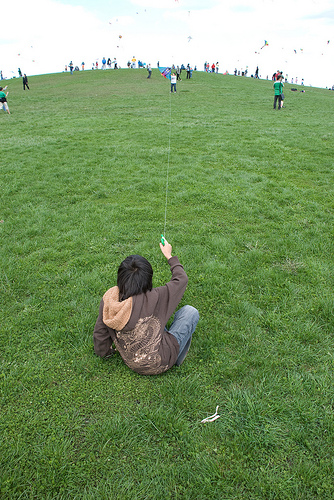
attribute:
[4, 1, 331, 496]
scene — including kite, about boy on grass, including bag, including black bag, including a bag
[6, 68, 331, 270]
grassy knoll — grass-covered, green in color, large grassy area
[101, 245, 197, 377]
boy — sitting, flying colorful kite, wearing brown, sitting on grass, person holding, holding a kite, wearing jacket, holding string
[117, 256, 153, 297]
hair — black in color, the hair of boy, boy's hair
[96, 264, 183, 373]
pullover — a boy's pullover, like shirt, brown sweater, brown jacket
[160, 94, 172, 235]
string — a string in scene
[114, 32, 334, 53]
flying kites — red blue, aqua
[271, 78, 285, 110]
person — positioned on grass, on grassy knoll, upon the grass, standing, carrying a bag, standing on hill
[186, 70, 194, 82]
child and person — standing child first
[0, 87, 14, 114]
man — wearing green, wearing shirt, wearing it on waist, wearing it tied, standing on hill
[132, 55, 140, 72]
distant person — wearing yellow, wearing shirt, standing on hill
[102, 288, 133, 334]
hood — part of sweater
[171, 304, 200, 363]
jeans — blue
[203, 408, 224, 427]
white string — on ground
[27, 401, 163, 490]
grass — below boy, green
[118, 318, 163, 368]
dragon — on boy's pullover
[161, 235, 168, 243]
something — kite spool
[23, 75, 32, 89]
person in black — standing on  hill, in background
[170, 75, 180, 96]
person in white — standing on hill, in background, wearing white shirt, possibly boy